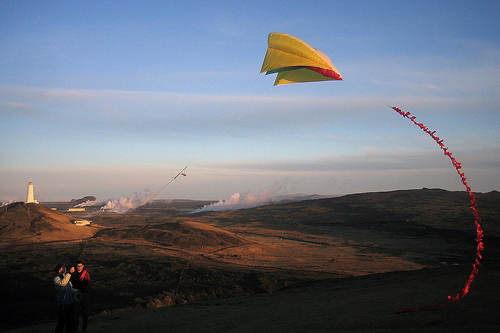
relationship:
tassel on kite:
[342, 106, 488, 312] [258, 28, 341, 88]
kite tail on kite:
[385, 107, 485, 316] [258, 28, 341, 88]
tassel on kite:
[342, 93, 487, 313] [258, 28, 341, 88]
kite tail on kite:
[385, 107, 485, 316] [258, 31, 488, 315]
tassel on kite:
[342, 106, 488, 312] [258, 31, 488, 315]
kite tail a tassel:
[385, 107, 485, 316] [342, 106, 488, 312]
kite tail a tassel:
[385, 88, 469, 200] [342, 106, 488, 312]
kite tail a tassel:
[385, 107, 485, 316] [456, 170, 466, 177]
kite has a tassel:
[258, 31, 488, 315] [456, 170, 466, 177]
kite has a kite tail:
[258, 31, 488, 315] [385, 107, 485, 316]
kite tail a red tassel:
[385, 107, 485, 316] [390, 100, 489, 309]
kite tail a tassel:
[385, 107, 485, 316] [475, 249, 482, 260]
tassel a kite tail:
[342, 106, 488, 312] [385, 107, 485, 316]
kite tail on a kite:
[385, 107, 485, 316] [265, 24, 343, 85]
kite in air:
[242, 12, 488, 304] [4, 1, 497, 120]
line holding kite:
[132, 137, 220, 215] [259, 32, 375, 125]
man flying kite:
[51, 264, 77, 315] [242, 12, 488, 304]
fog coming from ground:
[0, 246, 154, 315] [41, 192, 145, 296]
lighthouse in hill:
[22, 179, 38, 211] [0, 204, 90, 254]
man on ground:
[68, 262, 94, 296] [105, 310, 219, 331]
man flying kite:
[68, 262, 94, 296] [258, 31, 488, 315]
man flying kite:
[68, 262, 94, 296] [259, 30, 485, 309]